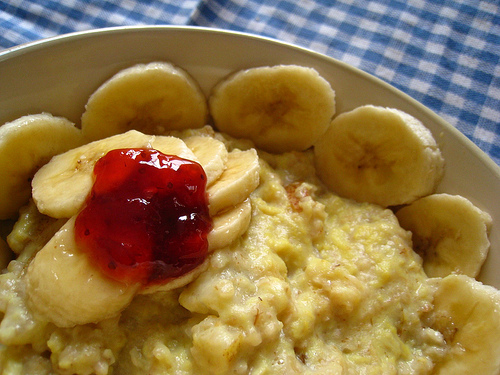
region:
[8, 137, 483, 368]
Oatmeal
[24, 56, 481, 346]
Bananas in the oatmeal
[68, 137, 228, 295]
Strawberry jam on some bananas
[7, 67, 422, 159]
Bananas around the perimeter of the bowl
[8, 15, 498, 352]
The oatmeal is served in a bowl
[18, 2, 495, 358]
The bowl is on a table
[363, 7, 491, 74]
Blue and white tablecloth on the table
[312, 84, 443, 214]
The bananas are cut into circles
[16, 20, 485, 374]
The bowl is circular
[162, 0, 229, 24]
Crease in the tablecloth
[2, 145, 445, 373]
Oatmeal in a bowl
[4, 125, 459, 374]
Oatmeal in a white bowl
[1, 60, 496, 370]
Bananas in a bowl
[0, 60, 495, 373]
Bananas in a white bowl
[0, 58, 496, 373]
Sliced bananas in a bowl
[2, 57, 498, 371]
Sliced bananas in a white bowl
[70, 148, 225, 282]
Strawberry jelly in a bowl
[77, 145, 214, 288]
Strawberry jelly in a white bowl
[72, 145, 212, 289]
Strawberry jelly on top of bananas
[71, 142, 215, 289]
Strawberry jelly on top of sliced bananas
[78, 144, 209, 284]
strawberry jelly on the bananas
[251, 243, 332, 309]
oatmeal in the bowl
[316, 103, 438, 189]
banana on the side of the bowl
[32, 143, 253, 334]
stack of bananas with jelly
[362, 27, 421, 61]
blue and white checkered cloth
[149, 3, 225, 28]
crease in the tablecloth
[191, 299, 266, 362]
chunks in the oatmeal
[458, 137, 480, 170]
part of the white bowl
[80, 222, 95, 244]
seed in the jelly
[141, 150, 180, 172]
shiny on top of the jelly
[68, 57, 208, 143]
slice of banana in a bowl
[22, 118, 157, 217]
slice of banana in a bowl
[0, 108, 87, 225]
slice of banana in a bowl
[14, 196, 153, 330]
slice of banana in a bowl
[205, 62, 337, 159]
slice of banana in a bowl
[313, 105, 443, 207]
slice of banana in a bowl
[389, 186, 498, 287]
slice of banana in a bowl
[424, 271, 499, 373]
slice of banana in a bowl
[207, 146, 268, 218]
slice of banana in a bowl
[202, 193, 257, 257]
slice of banana in a bowl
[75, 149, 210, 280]
glob of strawberry jam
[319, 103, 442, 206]
round banana slice in bowl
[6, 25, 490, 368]
food is in a round tan bowl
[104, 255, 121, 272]
strawberry seed in the jelly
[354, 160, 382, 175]
dark seeds in center of banana slice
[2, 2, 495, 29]
tablecloth is blue and white checkered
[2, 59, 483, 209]
bowl is lined with banana slices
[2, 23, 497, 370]
oatmeal with fruit on it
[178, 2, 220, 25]
tablecloth has a wrinkle in it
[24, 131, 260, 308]
jam is on top of banana slices